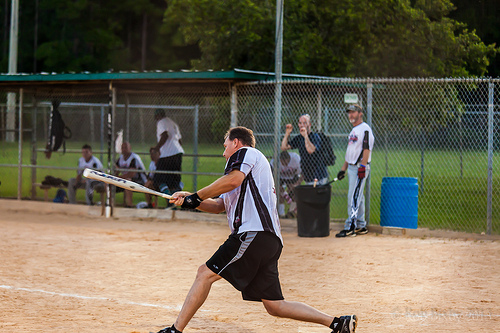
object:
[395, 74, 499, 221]
fence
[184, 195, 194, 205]
wristband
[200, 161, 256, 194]
arm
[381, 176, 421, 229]
trashcan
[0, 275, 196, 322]
chalk line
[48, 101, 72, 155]
bag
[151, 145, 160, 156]
hand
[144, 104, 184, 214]
man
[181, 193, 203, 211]
glove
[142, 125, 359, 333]
man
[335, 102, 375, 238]
man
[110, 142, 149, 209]
man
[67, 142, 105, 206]
man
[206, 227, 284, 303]
shorts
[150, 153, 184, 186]
shorts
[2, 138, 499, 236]
grass